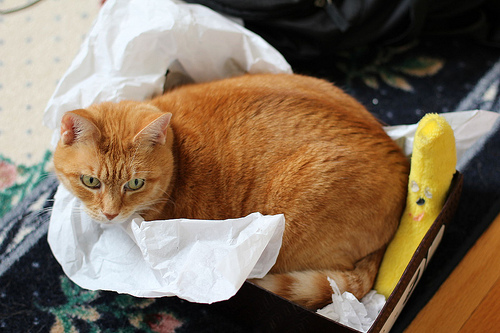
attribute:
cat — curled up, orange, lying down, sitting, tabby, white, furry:
[52, 70, 410, 315]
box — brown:
[159, 68, 464, 331]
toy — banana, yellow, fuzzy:
[375, 112, 458, 302]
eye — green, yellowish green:
[123, 174, 148, 193]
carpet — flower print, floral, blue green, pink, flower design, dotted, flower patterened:
[2, 1, 499, 332]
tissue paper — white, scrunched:
[47, 1, 499, 330]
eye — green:
[79, 172, 101, 191]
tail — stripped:
[249, 248, 384, 309]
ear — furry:
[132, 112, 174, 147]